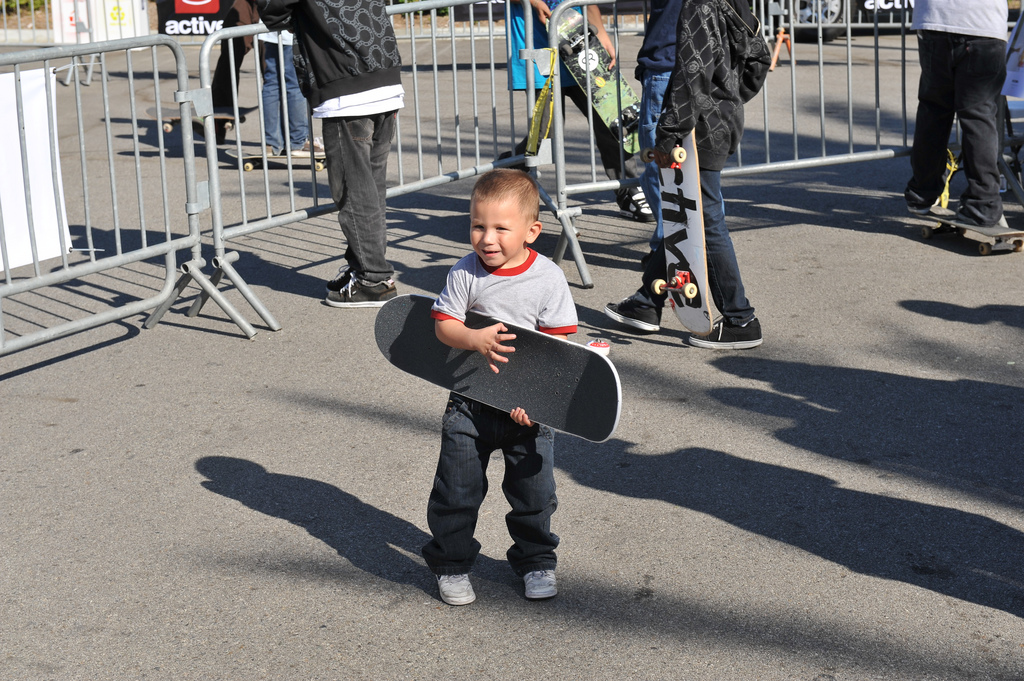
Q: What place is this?
A: It is a street.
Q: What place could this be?
A: It is a street.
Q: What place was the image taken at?
A: It was taken at the street.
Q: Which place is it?
A: It is a street.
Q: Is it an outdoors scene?
A: Yes, it is outdoors.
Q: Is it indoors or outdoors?
A: It is outdoors.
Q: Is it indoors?
A: No, it is outdoors.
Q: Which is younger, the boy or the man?
A: The boy is younger than the man.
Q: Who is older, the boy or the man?
A: The man is older than the boy.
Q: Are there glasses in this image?
A: No, there are no glasses.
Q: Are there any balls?
A: No, there are no balls.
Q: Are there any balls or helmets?
A: No, there are no balls or helmets.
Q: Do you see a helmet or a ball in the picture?
A: No, there are no balls or helmets.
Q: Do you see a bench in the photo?
A: No, there are no benches.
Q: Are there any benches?
A: No, there are no benches.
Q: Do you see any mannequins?
A: No, there are no mannequins.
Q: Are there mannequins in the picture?
A: No, there are no mannequins.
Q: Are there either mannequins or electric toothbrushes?
A: No, there are no mannequins or electric toothbrushes.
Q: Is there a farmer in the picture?
A: No, there are no farmers.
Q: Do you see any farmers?
A: No, there are no farmers.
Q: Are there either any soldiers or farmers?
A: No, there are no farmers or soldiers.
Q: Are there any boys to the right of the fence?
A: Yes, there is a boy to the right of the fence.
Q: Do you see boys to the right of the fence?
A: Yes, there is a boy to the right of the fence.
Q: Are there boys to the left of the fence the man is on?
A: No, the boy is to the right of the fence.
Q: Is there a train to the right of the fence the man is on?
A: No, there is a boy to the right of the fence.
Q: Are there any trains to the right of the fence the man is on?
A: No, there is a boy to the right of the fence.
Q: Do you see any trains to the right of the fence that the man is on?
A: No, there is a boy to the right of the fence.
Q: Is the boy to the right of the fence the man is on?
A: Yes, the boy is to the right of the fence.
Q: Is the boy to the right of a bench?
A: No, the boy is to the right of the fence.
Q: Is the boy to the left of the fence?
A: No, the boy is to the right of the fence.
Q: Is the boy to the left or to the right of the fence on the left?
A: The boy is to the right of the fence.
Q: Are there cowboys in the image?
A: No, there are no cowboys.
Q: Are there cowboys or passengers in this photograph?
A: No, there are no cowboys or passengers.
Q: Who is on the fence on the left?
A: The man is on the fence.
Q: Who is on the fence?
A: The man is on the fence.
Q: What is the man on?
A: The man is on the fence.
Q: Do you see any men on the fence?
A: Yes, there is a man on the fence.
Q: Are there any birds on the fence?
A: No, there is a man on the fence.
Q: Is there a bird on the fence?
A: No, there is a man on the fence.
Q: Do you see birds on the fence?
A: No, there is a man on the fence.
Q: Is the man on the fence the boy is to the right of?
A: Yes, the man is on the fence.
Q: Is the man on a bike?
A: No, the man is on the fence.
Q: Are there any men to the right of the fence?
A: Yes, there is a man to the right of the fence.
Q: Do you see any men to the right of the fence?
A: Yes, there is a man to the right of the fence.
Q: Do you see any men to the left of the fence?
A: No, the man is to the right of the fence.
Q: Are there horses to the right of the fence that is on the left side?
A: No, there is a man to the right of the fence.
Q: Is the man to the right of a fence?
A: Yes, the man is to the right of a fence.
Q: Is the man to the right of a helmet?
A: No, the man is to the right of a fence.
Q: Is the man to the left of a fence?
A: No, the man is to the right of a fence.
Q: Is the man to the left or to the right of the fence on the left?
A: The man is to the right of the fence.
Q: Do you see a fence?
A: Yes, there is a fence.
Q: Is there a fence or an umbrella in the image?
A: Yes, there is a fence.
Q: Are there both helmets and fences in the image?
A: No, there is a fence but no helmets.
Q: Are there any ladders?
A: No, there are no ladders.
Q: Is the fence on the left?
A: Yes, the fence is on the left of the image.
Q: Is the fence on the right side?
A: No, the fence is on the left of the image.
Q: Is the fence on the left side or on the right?
A: The fence is on the left of the image.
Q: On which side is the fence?
A: The fence is on the left of the image.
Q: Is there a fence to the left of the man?
A: Yes, there is a fence to the left of the man.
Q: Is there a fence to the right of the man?
A: No, the fence is to the left of the man.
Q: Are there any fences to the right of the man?
A: No, the fence is to the left of the man.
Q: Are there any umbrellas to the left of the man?
A: No, there is a fence to the left of the man.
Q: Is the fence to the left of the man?
A: Yes, the fence is to the left of the man.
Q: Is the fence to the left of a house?
A: No, the fence is to the left of the man.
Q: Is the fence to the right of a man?
A: No, the fence is to the left of a man.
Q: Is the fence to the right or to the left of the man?
A: The fence is to the left of the man.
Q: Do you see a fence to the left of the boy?
A: Yes, there is a fence to the left of the boy.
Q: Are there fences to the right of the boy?
A: No, the fence is to the left of the boy.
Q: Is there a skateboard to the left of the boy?
A: No, there is a fence to the left of the boy.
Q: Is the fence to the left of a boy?
A: Yes, the fence is to the left of a boy.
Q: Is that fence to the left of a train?
A: No, the fence is to the left of a boy.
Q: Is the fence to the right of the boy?
A: No, the fence is to the left of the boy.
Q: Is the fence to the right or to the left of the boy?
A: The fence is to the left of the boy.